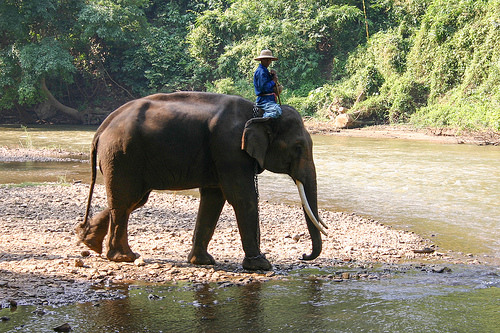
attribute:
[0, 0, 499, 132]
leaves — green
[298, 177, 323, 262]
trunk — long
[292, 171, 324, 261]
trunk — long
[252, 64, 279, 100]
blue shirt —  blue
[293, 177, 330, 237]
tusk — white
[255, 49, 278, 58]
hat — beige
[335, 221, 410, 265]
rocks — brown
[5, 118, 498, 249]
water — brown, moving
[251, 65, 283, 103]
shirt — blue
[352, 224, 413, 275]
rocks — brown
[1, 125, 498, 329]
water — brown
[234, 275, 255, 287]
rocks — brown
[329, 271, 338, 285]
rocks — brown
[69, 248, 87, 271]
rocks — brown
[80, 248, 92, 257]
rocks — brown